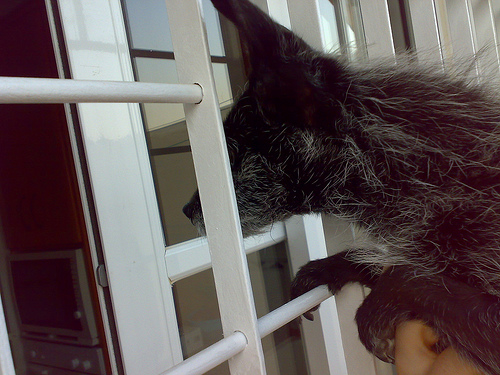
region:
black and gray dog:
[184, 5, 499, 363]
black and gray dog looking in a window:
[187, 3, 499, 365]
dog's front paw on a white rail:
[287, 250, 385, 317]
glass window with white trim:
[116, 2, 333, 374]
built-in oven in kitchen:
[5, 253, 113, 373]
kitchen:
[1, 2, 121, 374]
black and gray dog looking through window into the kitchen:
[183, 2, 498, 363]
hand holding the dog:
[396, 324, 479, 374]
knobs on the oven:
[30, 349, 93, 369]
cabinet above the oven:
[3, 103, 83, 247]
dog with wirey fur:
[188, 5, 495, 361]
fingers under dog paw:
[388, 309, 470, 374]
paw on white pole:
[168, 270, 344, 371]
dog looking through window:
[180, 108, 280, 244]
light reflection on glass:
[133, 25, 233, 128]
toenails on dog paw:
[294, 309, 317, 325]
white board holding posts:
[175, 25, 265, 372]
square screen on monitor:
[6, 255, 81, 336]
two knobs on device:
[65, 348, 95, 373]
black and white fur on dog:
[343, 52, 495, 265]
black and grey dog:
[194, 8, 494, 347]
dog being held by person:
[178, 10, 489, 374]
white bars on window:
[15, 15, 365, 365]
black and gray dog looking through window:
[177, 3, 494, 373]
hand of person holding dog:
[388, 317, 493, 372]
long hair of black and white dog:
[235, 53, 490, 281]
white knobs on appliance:
[19, 340, 92, 371]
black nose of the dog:
[180, 200, 196, 220]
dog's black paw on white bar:
[289, 258, 349, 315]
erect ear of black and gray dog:
[226, 5, 332, 92]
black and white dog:
[176, 14, 498, 363]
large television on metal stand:
[0, 236, 110, 373]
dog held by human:
[187, 0, 497, 374]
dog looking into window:
[134, 0, 499, 368]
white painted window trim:
[45, 0, 385, 373]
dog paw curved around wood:
[242, 235, 389, 346]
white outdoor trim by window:
[291, 3, 498, 139]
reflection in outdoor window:
[122, 1, 319, 369]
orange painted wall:
[4, 2, 106, 374]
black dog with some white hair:
[206, 10, 498, 368]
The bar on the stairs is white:
[2, 71, 200, 118]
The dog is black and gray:
[223, 9, 498, 371]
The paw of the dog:
[285, 241, 347, 330]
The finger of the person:
[384, 318, 435, 371]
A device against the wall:
[0, 243, 104, 352]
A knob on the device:
[69, 304, 84, 326]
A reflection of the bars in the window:
[126, 38, 253, 160]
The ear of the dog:
[210, 3, 355, 133]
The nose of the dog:
[168, 192, 202, 225]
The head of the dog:
[181, 2, 350, 252]